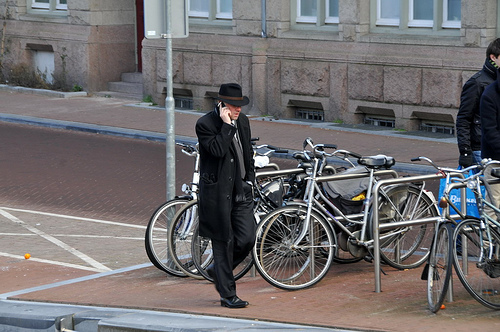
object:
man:
[194, 81, 259, 315]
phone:
[215, 99, 230, 114]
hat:
[207, 81, 251, 107]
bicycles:
[410, 152, 500, 315]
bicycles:
[427, 162, 500, 316]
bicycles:
[141, 141, 442, 290]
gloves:
[196, 172, 221, 185]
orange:
[438, 302, 448, 311]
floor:
[0, 199, 497, 331]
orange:
[21, 251, 33, 260]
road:
[1, 202, 219, 301]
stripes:
[0, 206, 205, 245]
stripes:
[1, 209, 113, 273]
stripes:
[0, 205, 199, 273]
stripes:
[1, 251, 109, 273]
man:
[454, 36, 500, 259]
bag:
[435, 165, 481, 225]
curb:
[0, 120, 468, 300]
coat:
[190, 109, 259, 241]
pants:
[206, 185, 257, 299]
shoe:
[220, 293, 250, 309]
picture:
[0, 0, 500, 331]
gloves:
[456, 151, 477, 168]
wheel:
[425, 220, 455, 314]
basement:
[162, 86, 457, 137]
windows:
[417, 114, 456, 135]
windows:
[360, 109, 395, 128]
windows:
[293, 104, 325, 122]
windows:
[164, 93, 193, 111]